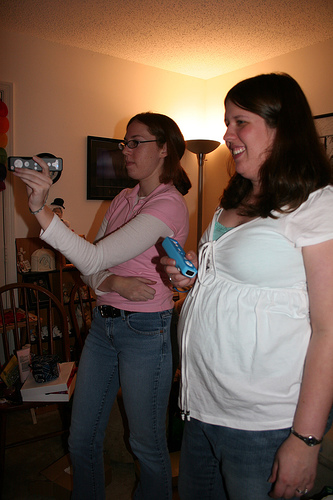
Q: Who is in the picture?
A: Two women.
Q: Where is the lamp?
A: In the distance between the two women.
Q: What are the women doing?
A: Playing a video game.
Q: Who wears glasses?
A: The woman on the left.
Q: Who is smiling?
A: The woman on the right.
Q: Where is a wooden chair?
A: To the left of the woman with glasses.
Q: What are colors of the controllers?
A: Silver and blue.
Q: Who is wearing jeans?
A: Both women.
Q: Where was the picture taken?
A: In a living room.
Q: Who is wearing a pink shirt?
A: A woman.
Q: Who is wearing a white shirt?
A: A woman.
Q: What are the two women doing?
A: Playing video games.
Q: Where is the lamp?
A: Behind the women.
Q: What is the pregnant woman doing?
A: Playing video games.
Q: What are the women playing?
A: The Wii.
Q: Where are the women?
A: In the living room.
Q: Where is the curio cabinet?
A: Next to the door.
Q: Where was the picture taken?
A: In a living room.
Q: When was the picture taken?
A: Nighttime.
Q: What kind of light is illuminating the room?
A: A lamp.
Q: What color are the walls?
A: Beige.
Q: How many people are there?
A: Two.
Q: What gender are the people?
A: Female.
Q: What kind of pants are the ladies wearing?
A: Jeans.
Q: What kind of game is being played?
A: Wii.